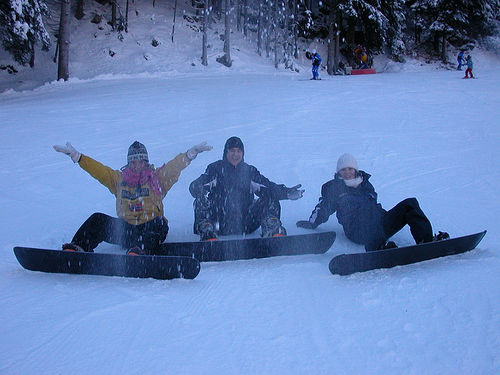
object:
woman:
[53, 136, 214, 257]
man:
[188, 136, 306, 242]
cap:
[335, 151, 359, 173]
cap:
[126, 141, 147, 162]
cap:
[223, 136, 245, 149]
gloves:
[295, 219, 319, 228]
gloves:
[53, 142, 81, 159]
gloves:
[286, 184, 305, 201]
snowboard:
[150, 230, 336, 262]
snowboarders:
[291, 150, 448, 251]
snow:
[0, 0, 499, 375]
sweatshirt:
[75, 152, 191, 227]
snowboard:
[328, 231, 485, 276]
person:
[351, 44, 374, 68]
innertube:
[350, 69, 377, 75]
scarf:
[124, 165, 160, 194]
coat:
[189, 159, 286, 214]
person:
[304, 51, 322, 80]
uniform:
[310, 54, 319, 67]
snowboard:
[11, 245, 200, 279]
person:
[458, 50, 476, 78]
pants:
[465, 67, 475, 77]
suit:
[305, 170, 388, 234]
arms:
[74, 151, 116, 194]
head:
[222, 136, 245, 165]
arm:
[253, 172, 285, 199]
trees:
[0, 0, 55, 71]